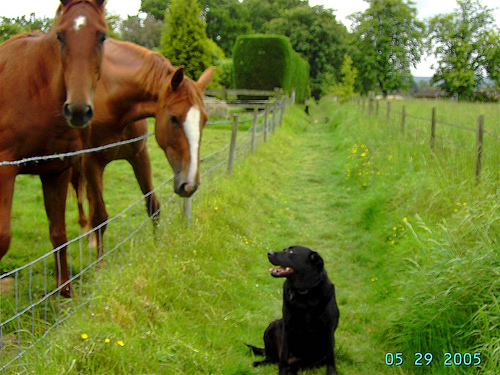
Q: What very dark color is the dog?
A: Black.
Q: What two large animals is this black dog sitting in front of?
A: Horses.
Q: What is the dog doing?
A: Sitting.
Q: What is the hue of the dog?
A: Black.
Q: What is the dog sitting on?
A: Grass.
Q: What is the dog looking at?
A: Horses.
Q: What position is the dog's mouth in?
A: Open.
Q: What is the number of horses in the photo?
A: Two.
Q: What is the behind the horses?
A: Shrubs.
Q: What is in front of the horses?
A: Fence.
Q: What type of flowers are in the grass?
A: Dandelions.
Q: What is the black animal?
A: Dog.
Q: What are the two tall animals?
A: Horses.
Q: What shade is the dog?
A: Black.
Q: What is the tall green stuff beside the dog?
A: Grass.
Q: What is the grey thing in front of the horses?
A: Fence.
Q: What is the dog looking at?
A: Horses.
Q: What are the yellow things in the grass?
A: Flowers.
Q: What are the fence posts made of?
A: Wood.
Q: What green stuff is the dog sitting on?
A: Grass.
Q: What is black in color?
A: Dog.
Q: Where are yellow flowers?
A: In the grass.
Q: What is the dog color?
A: Black.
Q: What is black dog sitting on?
A: Grass.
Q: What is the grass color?
A: Green.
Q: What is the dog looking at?
A: Horses.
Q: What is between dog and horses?
A: Wired fence.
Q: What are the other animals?
A: Horses.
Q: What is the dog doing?
A: Sitting.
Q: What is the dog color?
A: Black.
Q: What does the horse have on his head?
A: Blaze.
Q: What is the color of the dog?
A: Black.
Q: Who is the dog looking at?
A: The horses.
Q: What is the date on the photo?
A: 05 29 2005.